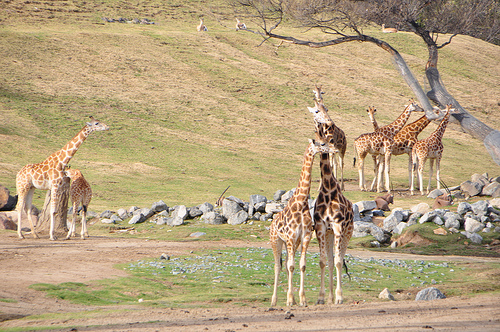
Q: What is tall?
A: The giraffe.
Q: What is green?
A: Grass.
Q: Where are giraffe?
A: On grassy field.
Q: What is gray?
A: Large rocks.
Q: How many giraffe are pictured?
A: Nine.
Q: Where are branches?
A: On a tree.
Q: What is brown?
A: Dirt on ground.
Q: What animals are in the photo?
A: Giraffes.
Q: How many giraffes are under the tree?
A: Four.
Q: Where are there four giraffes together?
A: Under the tree.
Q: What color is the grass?
A: Green.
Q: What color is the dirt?
A: Brown.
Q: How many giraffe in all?
A: Nine.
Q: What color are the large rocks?
A: Gray.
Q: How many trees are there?
A: One.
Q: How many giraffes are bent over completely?
A: One.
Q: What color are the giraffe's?
A: Brown and white.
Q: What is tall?
A: The giraffes.